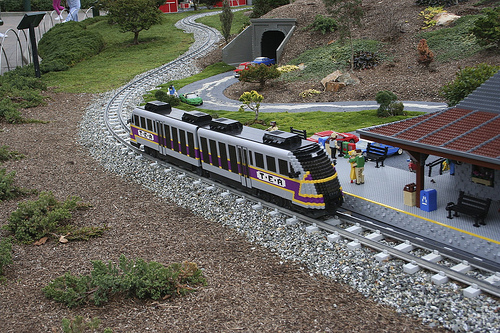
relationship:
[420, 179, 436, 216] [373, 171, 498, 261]
recycle bin in platform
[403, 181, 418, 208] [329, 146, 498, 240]
trash can in platform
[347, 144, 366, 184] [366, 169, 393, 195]
person in platform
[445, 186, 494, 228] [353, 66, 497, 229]
bench in station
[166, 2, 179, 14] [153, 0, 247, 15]
door in building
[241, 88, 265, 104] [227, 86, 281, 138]
leaves in tree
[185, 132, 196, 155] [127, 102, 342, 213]
window on train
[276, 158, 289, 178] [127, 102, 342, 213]
window on train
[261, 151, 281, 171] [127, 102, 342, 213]
window on train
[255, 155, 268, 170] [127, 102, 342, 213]
window on train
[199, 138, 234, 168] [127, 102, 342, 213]
window on train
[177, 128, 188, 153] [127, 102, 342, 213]
window on train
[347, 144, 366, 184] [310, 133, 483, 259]
person on platform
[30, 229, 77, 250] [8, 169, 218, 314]
leaves on ground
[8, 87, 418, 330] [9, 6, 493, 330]
brown dirt on ground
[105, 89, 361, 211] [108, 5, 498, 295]
train on track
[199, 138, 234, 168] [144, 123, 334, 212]
window on train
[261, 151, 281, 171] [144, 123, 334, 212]
window on train